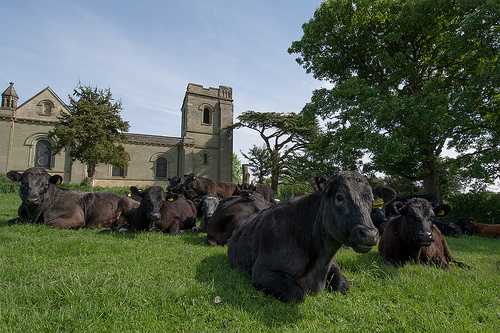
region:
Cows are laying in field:
[10, 128, 495, 323]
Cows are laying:
[9, 133, 489, 312]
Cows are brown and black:
[12, 139, 497, 327]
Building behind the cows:
[7, 66, 268, 206]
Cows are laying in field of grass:
[5, 178, 495, 331]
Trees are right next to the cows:
[253, 3, 498, 211]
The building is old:
[5, 67, 260, 199]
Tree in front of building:
[42, 68, 146, 186]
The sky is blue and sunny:
[3, 0, 495, 200]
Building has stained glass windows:
[26, 129, 213, 192]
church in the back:
[1, 83, 233, 184]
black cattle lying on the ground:
[0, 165, 468, 310]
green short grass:
[8, 168, 497, 331]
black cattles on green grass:
[2, 165, 456, 304]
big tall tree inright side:
[287, 3, 493, 230]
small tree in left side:
[49, 80, 131, 187]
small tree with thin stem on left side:
[245, 113, 319, 196]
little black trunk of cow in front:
[341, 211, 376, 253]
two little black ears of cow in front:
[311, 166, 393, 202]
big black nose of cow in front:
[359, 223, 382, 241]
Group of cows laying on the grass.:
[1, 164, 473, 309]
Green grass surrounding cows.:
[9, 173, 491, 329]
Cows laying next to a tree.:
[424, 174, 498, 242]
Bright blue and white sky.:
[2, 2, 289, 81]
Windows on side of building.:
[27, 136, 179, 178]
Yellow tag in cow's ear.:
[370, 194, 387, 211]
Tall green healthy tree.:
[290, 4, 497, 221]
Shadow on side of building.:
[155, 127, 242, 187]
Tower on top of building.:
[1, 79, 24, 114]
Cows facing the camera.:
[2, 164, 452, 321]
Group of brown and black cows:
[12, 146, 474, 321]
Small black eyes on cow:
[332, 188, 379, 213]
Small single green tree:
[46, 83, 133, 191]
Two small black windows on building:
[187, 93, 231, 192]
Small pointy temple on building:
[1, 79, 31, 126]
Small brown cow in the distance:
[464, 200, 499, 243]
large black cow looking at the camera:
[210, 150, 390, 314]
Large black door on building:
[21, 131, 73, 181]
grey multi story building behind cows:
[3, 50, 248, 252]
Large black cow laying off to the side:
[3, 156, 143, 241]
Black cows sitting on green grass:
[19, 141, 463, 303]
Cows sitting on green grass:
[15, 155, 448, 305]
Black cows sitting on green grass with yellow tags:
[12, 153, 469, 289]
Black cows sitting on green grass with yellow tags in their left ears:
[9, 144, 450, 302]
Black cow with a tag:
[223, 161, 399, 307]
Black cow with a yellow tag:
[230, 162, 402, 313]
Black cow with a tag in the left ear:
[237, 150, 397, 315]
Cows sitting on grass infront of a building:
[0, 67, 491, 302]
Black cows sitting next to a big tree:
[301, 2, 497, 328]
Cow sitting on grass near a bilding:
[7, 83, 120, 233]